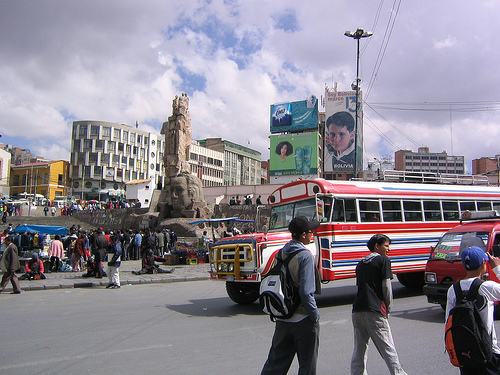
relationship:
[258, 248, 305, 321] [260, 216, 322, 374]
backpack on man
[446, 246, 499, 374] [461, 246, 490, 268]
boy wearing baseball cap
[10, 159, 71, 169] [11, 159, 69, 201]
roof on house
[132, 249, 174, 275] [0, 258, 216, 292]
person sitting on sidewalk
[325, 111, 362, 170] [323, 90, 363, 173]
person on billboard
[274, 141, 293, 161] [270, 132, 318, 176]
person on billboard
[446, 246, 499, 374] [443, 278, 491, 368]
boy wearing a backpack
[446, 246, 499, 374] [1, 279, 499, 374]
boy walking on street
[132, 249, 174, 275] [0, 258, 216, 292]
person on sidewalk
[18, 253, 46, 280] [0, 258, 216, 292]
person on sidewalk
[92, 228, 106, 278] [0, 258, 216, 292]
person on sidewalk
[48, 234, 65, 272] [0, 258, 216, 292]
person on sidewalk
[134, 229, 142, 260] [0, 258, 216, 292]
person on sidewalk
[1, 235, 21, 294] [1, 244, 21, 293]
man wearing a suit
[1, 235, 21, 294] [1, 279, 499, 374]
man walking on street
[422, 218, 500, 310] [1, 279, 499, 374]
vehicle on street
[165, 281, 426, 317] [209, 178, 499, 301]
shadow from bus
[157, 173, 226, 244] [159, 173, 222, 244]
bust of a man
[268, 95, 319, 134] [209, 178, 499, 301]
billboard behind bus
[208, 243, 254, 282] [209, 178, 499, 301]
grill on bus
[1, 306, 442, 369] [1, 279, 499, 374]
line on street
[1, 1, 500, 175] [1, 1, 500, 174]
clouds in sky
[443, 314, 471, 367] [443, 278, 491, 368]
orange on backpack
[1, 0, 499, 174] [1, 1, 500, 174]
blue in sky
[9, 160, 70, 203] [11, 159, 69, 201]
stripes on house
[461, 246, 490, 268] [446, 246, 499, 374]
baseball cap on boy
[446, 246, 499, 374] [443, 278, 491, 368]
boy carrying backpack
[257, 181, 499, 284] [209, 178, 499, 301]
side of bus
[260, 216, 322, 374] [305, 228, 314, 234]
man wearing glasses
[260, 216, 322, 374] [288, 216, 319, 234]
man wearing cap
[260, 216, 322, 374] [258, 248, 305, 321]
man carrying backpack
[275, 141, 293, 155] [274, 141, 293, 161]
hair on person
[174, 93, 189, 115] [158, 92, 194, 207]
figures on statue